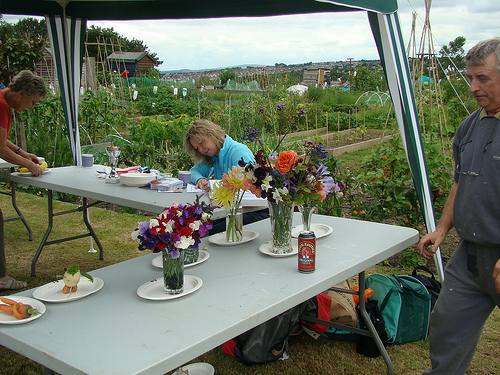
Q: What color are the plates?
A: White.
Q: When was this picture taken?
A: Daytime.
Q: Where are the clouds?
A: In the sky.